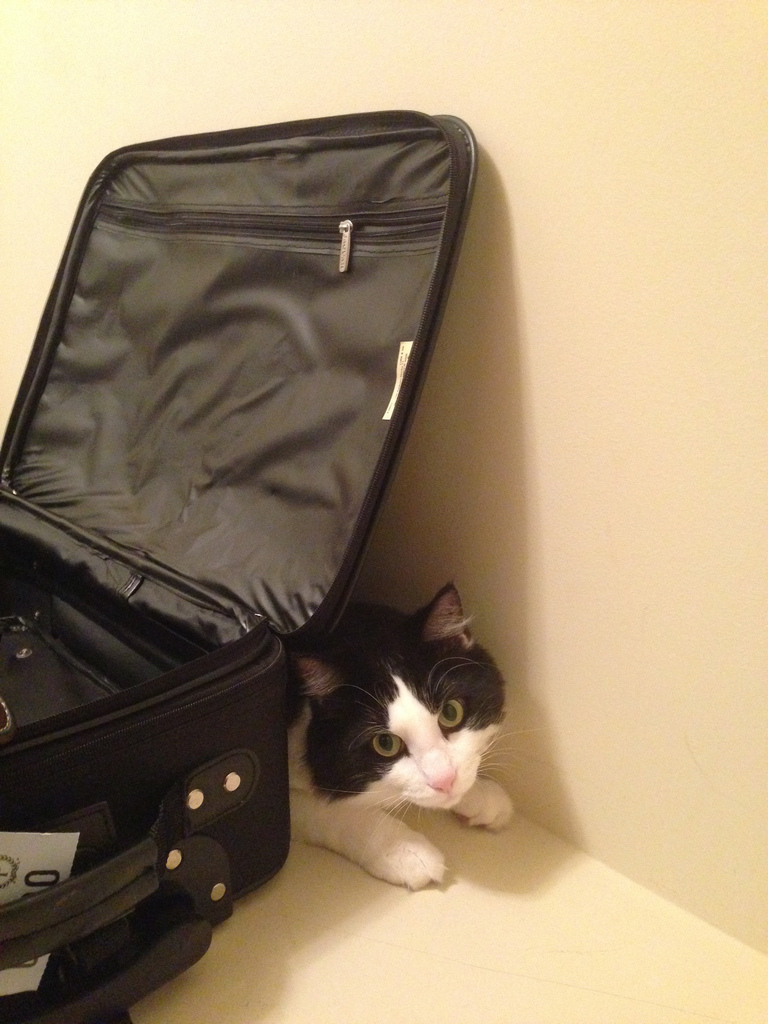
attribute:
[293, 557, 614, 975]
cat — black, white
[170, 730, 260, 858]
rivets — metal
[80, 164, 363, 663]
leather — black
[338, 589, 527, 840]
face — black, white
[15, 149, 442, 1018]
suitcase — black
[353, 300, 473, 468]
tag — white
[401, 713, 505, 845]
nose — pink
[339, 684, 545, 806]
eyes — green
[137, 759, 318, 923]
trim — silver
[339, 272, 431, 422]
tag — silver